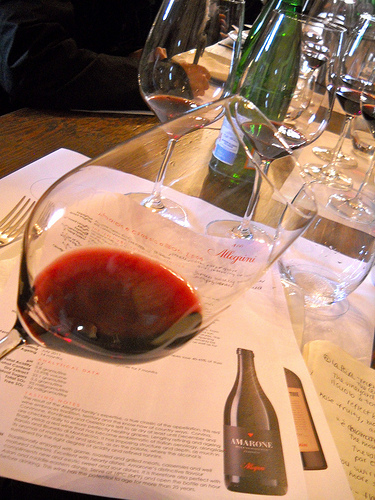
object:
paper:
[0, 190, 309, 498]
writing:
[0, 306, 223, 492]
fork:
[0, 197, 38, 251]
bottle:
[209, 0, 306, 193]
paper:
[301, 337, 375, 499]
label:
[212, 115, 249, 166]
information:
[0, 188, 375, 500]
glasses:
[0, 0, 375, 364]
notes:
[301, 332, 374, 499]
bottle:
[8, 180, 36, 250]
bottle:
[282, 367, 330, 473]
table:
[7, 19, 371, 488]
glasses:
[124, 2, 244, 228]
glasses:
[205, 0, 347, 257]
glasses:
[268, 181, 375, 322]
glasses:
[0, 96, 320, 359]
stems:
[150, 139, 180, 200]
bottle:
[223, 347, 287, 498]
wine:
[22, 245, 204, 360]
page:
[301, 340, 375, 499]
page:
[0, 192, 356, 500]